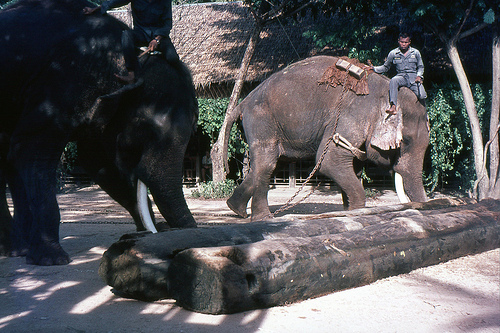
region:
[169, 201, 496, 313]
huge tree log laying near elephant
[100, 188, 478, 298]
huge log laying near elephant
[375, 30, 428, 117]
man sitting on top of elephant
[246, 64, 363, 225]
long chain attached to elephant's back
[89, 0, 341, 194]
large straw hut sitting in background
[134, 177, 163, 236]
long white tusk on elephant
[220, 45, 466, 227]
this is an elephant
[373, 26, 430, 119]
this is a man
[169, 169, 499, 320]
this is a log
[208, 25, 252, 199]
this is a tree trunk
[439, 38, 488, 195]
this is a tree trunk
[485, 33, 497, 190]
this is a tree trunk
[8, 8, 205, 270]
this is an elephant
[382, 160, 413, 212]
this is an elephant task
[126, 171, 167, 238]
this is an elephant task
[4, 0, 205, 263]
Dark elephant in shade.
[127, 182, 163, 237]
White elephant tusk.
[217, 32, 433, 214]
Man sitting on elephant.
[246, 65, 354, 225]
Silver chain on elephant.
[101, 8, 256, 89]
Straw roof for hut.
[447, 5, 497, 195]
Thin tree trunks on right.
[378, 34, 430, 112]
Man wearing blue clothing and brown shoes.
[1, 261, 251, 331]
Large shadow on gound.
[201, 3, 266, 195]
Dead tree behind elephant.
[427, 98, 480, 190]
Green leafy bush behind tree.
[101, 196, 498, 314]
wood poles horizontal on dirt surface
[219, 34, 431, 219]
man sitting on elephant head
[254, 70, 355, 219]
chain across elephant body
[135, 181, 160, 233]
white ivory elephant tusks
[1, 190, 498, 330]
light and shadows on ground surface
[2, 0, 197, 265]
person sitting on top of elephant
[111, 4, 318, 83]
thatched roof of building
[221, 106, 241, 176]
tail on back of elephant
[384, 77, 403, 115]
bare foot under pant leg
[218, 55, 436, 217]
chained up elephant with a man on it's back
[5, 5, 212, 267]
elephant using it's trunk to move a log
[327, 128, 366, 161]
part of a harness chained to an elephant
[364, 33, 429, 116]
man in a blue suit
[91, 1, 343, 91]
thatched roof of a building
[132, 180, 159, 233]
ivory tusk of an elephant